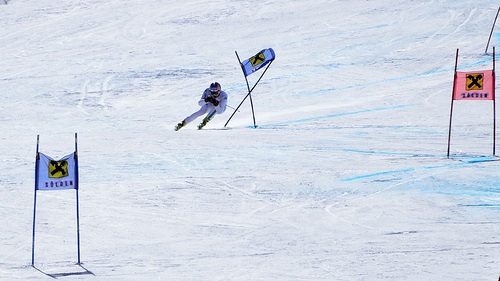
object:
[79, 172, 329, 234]
ice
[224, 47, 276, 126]
post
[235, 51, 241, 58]
edge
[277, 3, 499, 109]
snow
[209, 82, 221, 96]
helmet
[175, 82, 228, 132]
skier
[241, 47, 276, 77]
flag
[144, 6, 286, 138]
snow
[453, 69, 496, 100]
flag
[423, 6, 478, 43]
tracks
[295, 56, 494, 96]
line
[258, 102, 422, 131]
line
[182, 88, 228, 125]
outfit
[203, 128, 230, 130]
shadow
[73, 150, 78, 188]
edge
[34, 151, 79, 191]
sign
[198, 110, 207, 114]
knee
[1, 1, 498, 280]
hill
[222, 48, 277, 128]
markder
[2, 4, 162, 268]
snow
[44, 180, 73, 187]
lettering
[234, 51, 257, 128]
poles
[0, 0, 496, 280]
ground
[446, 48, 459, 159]
pole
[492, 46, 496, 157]
pole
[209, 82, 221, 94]
head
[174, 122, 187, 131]
skiis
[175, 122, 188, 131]
feet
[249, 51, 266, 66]
logo